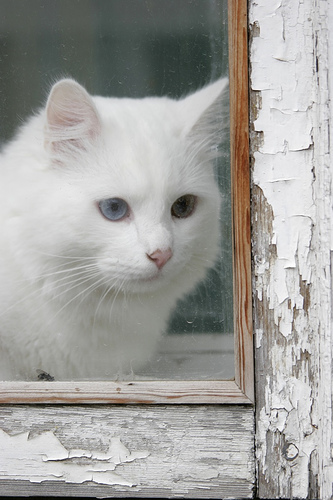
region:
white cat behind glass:
[8, 70, 231, 380]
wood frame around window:
[2, 82, 252, 404]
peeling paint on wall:
[247, 0, 332, 285]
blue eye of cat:
[100, 196, 128, 219]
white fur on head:
[107, 97, 179, 191]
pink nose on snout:
[150, 247, 172, 267]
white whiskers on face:
[24, 254, 135, 327]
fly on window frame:
[34, 368, 56, 381]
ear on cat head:
[44, 79, 99, 149]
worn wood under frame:
[2, 404, 255, 495]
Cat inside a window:
[38, 95, 234, 275]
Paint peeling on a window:
[247, 296, 332, 495]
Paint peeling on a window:
[21, 408, 260, 493]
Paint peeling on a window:
[268, 326, 332, 457]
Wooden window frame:
[264, 316, 330, 494]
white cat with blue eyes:
[92, 181, 209, 258]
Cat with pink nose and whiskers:
[73, 169, 200, 299]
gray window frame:
[7, 399, 323, 472]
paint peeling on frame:
[25, 422, 328, 485]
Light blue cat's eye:
[92, 196, 131, 222]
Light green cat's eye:
[165, 191, 203, 223]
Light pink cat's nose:
[146, 248, 177, 270]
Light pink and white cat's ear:
[42, 81, 97, 148]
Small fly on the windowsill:
[32, 366, 59, 386]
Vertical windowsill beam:
[232, 2, 251, 402]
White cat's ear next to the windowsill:
[178, 75, 229, 141]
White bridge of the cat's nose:
[141, 223, 177, 253]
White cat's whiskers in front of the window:
[6, 244, 129, 333]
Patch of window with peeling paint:
[0, 409, 253, 498]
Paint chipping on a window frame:
[248, 100, 316, 173]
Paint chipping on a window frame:
[31, 424, 263, 491]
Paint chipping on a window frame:
[260, 364, 331, 489]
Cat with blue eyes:
[101, 190, 199, 249]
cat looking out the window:
[45, 137, 221, 379]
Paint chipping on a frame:
[245, 23, 332, 148]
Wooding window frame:
[235, 197, 328, 402]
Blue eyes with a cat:
[83, 171, 210, 254]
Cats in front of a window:
[38, 94, 242, 374]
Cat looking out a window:
[21, 121, 309, 477]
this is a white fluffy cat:
[11, 70, 221, 373]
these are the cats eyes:
[84, 189, 213, 229]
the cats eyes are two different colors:
[83, 184, 217, 233]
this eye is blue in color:
[78, 180, 140, 232]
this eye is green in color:
[164, 178, 203, 231]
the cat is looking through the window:
[30, 42, 234, 331]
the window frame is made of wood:
[243, 90, 321, 410]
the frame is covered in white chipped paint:
[253, 74, 318, 358]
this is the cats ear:
[39, 58, 106, 171]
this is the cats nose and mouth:
[114, 233, 195, 291]